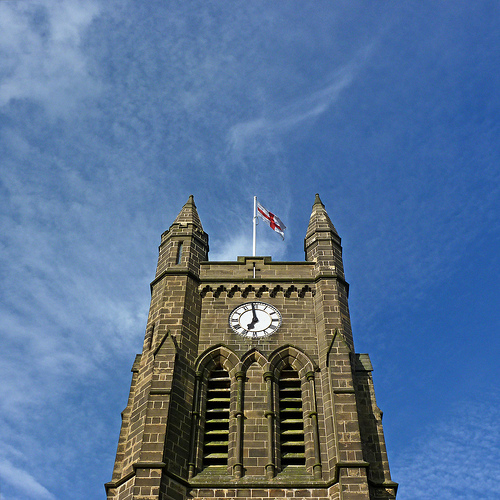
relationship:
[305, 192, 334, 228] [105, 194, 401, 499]
point on top of building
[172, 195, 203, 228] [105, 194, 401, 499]
point on top building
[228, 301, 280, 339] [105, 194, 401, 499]
clock mounted on building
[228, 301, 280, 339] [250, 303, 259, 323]
clock has minute hand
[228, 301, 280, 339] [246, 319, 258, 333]
clock has hour hand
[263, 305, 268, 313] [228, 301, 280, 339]
number one attached to clock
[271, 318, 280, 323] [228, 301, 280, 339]
number three visible on clock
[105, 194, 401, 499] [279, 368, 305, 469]
building has window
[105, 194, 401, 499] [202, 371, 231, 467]
building has window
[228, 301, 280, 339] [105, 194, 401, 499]
clock located on building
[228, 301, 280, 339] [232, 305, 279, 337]
clock has roman numerals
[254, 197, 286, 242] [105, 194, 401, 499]
flag on top of building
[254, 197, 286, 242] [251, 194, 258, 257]
flag attached to pole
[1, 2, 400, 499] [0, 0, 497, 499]
clouds floating in sky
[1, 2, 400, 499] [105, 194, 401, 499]
clouds behind building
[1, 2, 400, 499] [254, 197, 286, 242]
clouds behind flag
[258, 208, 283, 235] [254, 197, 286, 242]
cross printed on flag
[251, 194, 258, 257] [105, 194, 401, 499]
pole on top of building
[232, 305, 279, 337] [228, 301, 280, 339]
roman numerals visible on clock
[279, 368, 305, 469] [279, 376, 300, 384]
window has slit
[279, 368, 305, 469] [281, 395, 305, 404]
window has slit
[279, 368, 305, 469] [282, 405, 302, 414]
window has slit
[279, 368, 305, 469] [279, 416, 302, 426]
window has slit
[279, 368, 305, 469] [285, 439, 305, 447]
window has slit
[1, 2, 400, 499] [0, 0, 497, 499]
clouds against sky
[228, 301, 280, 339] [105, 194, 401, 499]
clock attached to building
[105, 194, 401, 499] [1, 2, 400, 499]
building beneath clouds